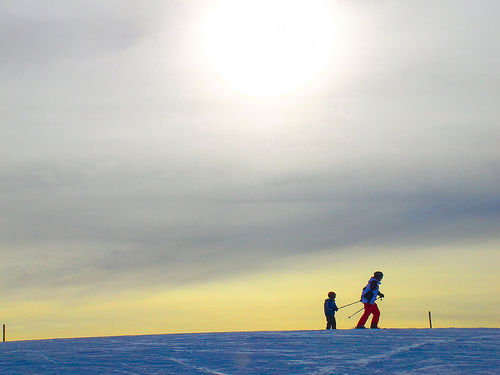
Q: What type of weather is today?
A: It is cloudy.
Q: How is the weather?
A: It is cloudy.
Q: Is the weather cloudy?
A: Yes, it is cloudy.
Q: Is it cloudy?
A: Yes, it is cloudy.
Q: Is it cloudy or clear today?
A: It is cloudy.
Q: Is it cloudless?
A: No, it is cloudy.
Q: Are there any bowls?
A: No, there are no bowls.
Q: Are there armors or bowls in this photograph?
A: No, there are no bowls or armors.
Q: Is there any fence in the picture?
A: No, there are no fences.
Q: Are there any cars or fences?
A: No, there are no fences or cars.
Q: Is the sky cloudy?
A: Yes, the sky is cloudy.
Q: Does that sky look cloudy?
A: Yes, the sky is cloudy.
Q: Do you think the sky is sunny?
A: No, the sky is cloudy.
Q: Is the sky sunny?
A: No, the sky is cloudy.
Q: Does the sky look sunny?
A: No, the sky is cloudy.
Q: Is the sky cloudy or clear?
A: The sky is cloudy.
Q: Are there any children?
A: Yes, there is a child.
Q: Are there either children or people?
A: Yes, there is a child.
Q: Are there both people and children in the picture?
A: Yes, there are both a child and people.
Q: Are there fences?
A: No, there are no fences.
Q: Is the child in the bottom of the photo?
A: Yes, the child is in the bottom of the image.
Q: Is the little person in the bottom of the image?
A: Yes, the child is in the bottom of the image.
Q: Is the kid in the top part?
A: No, the kid is in the bottom of the image.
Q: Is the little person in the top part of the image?
A: No, the kid is in the bottom of the image.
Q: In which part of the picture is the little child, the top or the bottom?
A: The child is in the bottom of the image.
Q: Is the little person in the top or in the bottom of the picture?
A: The child is in the bottom of the image.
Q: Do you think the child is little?
A: Yes, the child is little.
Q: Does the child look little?
A: Yes, the child is little.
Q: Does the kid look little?
A: Yes, the kid is little.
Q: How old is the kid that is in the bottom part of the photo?
A: The child is little.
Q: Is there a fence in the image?
A: No, there are no fences.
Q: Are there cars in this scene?
A: No, there are no cars.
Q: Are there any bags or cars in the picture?
A: No, there are no cars or bags.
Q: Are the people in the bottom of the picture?
A: Yes, the people are in the bottom of the image.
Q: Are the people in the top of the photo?
A: No, the people are in the bottom of the image.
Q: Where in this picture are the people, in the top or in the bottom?
A: The people are in the bottom of the image.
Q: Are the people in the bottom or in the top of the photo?
A: The people are in the bottom of the image.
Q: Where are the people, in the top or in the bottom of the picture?
A: The people are in the bottom of the image.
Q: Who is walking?
A: The people are walking.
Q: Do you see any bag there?
A: No, there are no bags.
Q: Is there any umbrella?
A: No, there are no umbrellas.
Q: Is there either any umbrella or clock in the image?
A: No, there are no umbrellas or clocks.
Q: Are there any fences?
A: No, there are no fences.